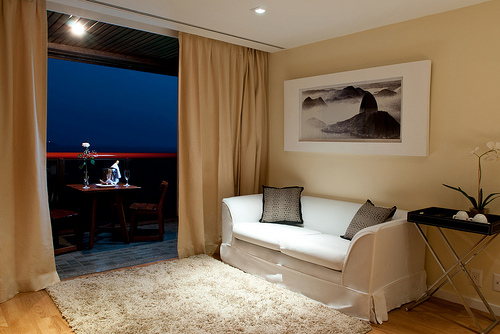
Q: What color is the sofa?
A: White.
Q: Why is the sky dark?
A: It is night time.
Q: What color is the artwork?
A: Black and white.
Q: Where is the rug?
A: In front of the sofa.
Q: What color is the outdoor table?
A: Brown.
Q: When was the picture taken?
A: At night.